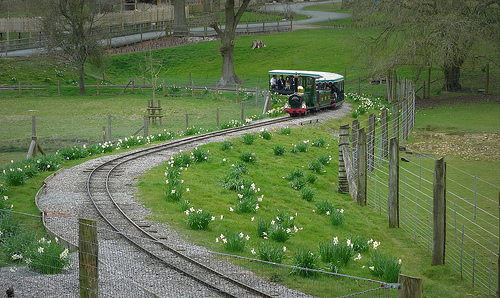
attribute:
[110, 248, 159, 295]
gravel — grey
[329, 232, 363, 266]
flower — white 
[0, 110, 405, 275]
flowers — white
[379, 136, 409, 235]
post — brown, wooden